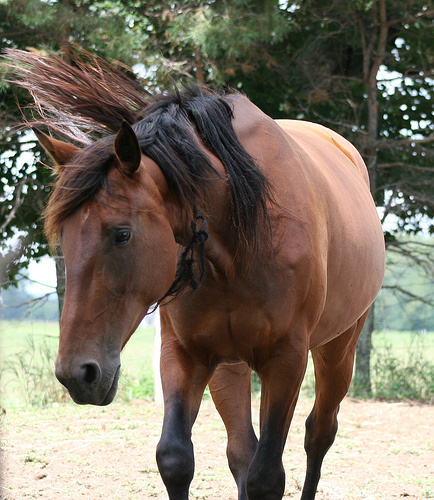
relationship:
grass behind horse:
[2, 320, 434, 410] [30, 91, 387, 500]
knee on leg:
[158, 441, 192, 491] [157, 307, 214, 500]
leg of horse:
[157, 307, 214, 500] [30, 91, 387, 500]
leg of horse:
[210, 361, 259, 500] [30, 91, 387, 500]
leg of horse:
[241, 346, 308, 500] [30, 91, 387, 500]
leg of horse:
[302, 314, 366, 500] [30, 91, 387, 500]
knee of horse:
[246, 464, 285, 500] [30, 91, 387, 500]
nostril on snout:
[81, 363, 96, 386] [54, 345, 121, 407]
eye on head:
[114, 228, 133, 243] [32, 119, 179, 406]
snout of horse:
[54, 345, 121, 407] [30, 91, 387, 500]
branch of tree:
[386, 10, 434, 23] [352, 2, 393, 392]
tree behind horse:
[352, 2, 393, 392] [30, 91, 387, 500]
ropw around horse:
[321, 133, 359, 168] [30, 91, 387, 500]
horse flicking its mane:
[30, 91, 387, 500] [2, 37, 276, 260]